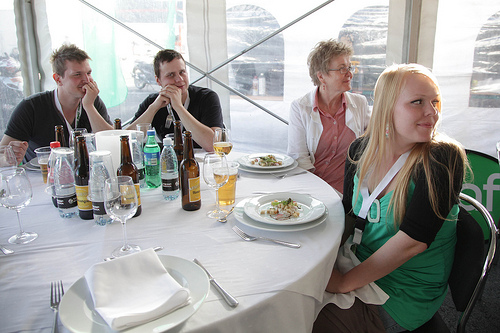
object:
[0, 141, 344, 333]
table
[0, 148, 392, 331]
cloth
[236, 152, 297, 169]
plates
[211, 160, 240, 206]
glass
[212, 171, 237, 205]
drink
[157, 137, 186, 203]
bottles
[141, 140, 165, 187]
drinks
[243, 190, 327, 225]
plate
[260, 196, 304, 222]
salad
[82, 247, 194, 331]
napkin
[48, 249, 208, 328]
plate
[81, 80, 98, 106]
left hand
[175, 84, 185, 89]
mouth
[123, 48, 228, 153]
guys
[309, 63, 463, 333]
woman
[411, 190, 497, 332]
chair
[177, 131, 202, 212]
bottle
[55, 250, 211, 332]
setting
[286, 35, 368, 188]
woman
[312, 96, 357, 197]
shirt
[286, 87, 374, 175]
sweater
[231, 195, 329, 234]
plates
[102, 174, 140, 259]
glasses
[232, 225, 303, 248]
fork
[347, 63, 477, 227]
hair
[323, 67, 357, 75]
glasses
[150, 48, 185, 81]
hair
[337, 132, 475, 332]
shirt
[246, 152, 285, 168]
meal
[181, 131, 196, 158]
neck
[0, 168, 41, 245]
glass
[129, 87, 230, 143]
shirt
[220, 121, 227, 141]
chair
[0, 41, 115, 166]
men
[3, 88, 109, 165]
shirts